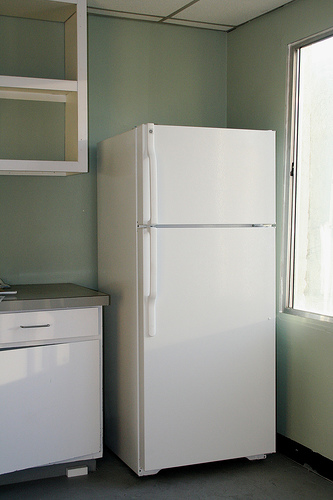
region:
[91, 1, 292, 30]
white square ceiling tiles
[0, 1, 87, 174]
cabinet with no doors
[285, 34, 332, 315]
light shining through window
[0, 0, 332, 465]
green walls of kitchen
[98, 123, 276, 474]
doors on white refrigerator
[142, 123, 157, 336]
two vertical white handles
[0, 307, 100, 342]
white drawer with handle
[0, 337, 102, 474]
open door of cupboard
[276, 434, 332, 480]
molding on bottom of wall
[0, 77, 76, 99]
shelf inside of cupboard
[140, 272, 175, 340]
White handle on fridge.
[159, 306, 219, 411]
Door on fridge is white.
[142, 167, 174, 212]
Handle on freezer is white.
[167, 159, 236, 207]
Freezer door is white.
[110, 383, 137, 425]
Side of fridge is white.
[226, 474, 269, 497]
Floor in room is gray.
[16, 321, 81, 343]
Silver handle on drawer.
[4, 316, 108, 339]
Drawer is white in color.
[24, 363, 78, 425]
Cabinet is white in color.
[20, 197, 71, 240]
Wall is painted green.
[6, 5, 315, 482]
kitchen with cabinets and refrigerator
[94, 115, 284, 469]
white refrigerator with top freezer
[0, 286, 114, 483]
white cabinets with grey counter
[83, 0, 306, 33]
white cieling tiles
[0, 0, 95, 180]
white open cabinets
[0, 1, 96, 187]
white cabinets without doors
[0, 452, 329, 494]
grey flooring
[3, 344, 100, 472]
bottom cabinet slightly open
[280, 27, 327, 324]
window on the left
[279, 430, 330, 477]
black border along the wall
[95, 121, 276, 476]
Large white refrigerator next to window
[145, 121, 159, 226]
Refrigerator handle is white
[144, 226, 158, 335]
Refrigerator handle is white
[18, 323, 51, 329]
Silver handle on white drawer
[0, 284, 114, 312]
Gray counter top next to refrigerator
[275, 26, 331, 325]
Large window on green wall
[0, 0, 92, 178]
White cabinetry above drawer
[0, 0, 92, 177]
Cabinetry next to white refrigerator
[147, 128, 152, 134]
Screw on refrigerator handle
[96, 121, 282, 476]
Refrigerator against green wall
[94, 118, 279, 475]
white refrigerator on corner of kitchen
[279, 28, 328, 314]
long window in silver frame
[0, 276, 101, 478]
grey counter over drawer and cabinet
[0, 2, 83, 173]
white frame of overhead cabinets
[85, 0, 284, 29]
white ceiling tiles over dark frame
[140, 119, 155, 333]
white handles on left side of door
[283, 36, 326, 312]
bright light coming through window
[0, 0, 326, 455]
kitchen walls painted a minty green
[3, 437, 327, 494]
worn gray floor covering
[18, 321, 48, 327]
thin metal handle on drawer